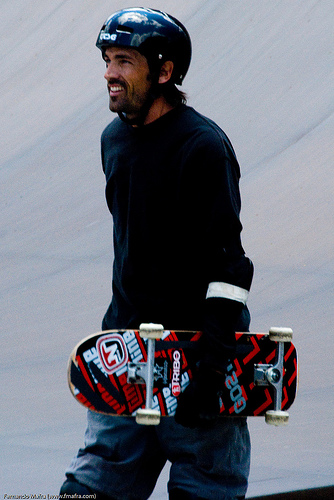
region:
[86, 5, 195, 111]
a black helmet is worn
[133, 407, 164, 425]
a white skateboard wheel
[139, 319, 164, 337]
a white skateboard wheel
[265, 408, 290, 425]
a white skateboard wheel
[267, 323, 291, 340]
a white skateboard wheel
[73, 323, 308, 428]
a colored skateboard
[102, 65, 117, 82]
a person's nose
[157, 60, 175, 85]
a person's ear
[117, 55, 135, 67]
a person's eye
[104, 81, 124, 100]
a person's mouth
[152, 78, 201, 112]
Long hair hanging down the nape of a man's neck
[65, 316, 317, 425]
A red, black, and white skateboard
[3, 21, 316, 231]
A half pipe behind a man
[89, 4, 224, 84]
A black helmet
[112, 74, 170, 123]
A helmet's strap hanging under a man's chin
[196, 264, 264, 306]
A white stripe on a man's arm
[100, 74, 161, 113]
A moustache and beard on a man's face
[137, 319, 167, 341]
A white wheel on a skateboard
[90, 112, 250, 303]
A black shirt on a man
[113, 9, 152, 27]
Light reflecting off a helmet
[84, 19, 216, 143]
Man with a helmet.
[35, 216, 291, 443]
Man holding the skateboard.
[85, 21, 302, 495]
Man wearing jeans and holding a skateboard.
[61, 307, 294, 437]
Black and red skateboard.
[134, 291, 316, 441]
Wheels on the skateboard.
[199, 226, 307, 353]
White stripe on the black shirt.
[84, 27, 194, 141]
Beard on the man.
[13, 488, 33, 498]
Words on the photo.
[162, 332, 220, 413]
Words on the skateboard.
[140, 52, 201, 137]
Long hair on the man.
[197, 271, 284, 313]
white band on black shirt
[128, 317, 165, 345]
white wheels on skateboard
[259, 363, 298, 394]
black screw on bottom of skateboard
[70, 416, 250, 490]
man wearing crumpled blue jeans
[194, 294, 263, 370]
black gloves on man's hand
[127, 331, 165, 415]
silver bracket on skate board wheel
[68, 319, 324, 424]
large skateboard in man's hand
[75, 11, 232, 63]
helmet on man's head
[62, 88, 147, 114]
beard on man's face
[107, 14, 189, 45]
shine on the black helmet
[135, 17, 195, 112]
man is wearing a helmet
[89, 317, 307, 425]
man is carrying a skateboard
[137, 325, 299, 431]
the wheels are white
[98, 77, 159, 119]
man has a beard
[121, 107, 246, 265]
man is wearing a black shirt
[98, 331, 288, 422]
the skateboard is black, red, and white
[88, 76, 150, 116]
the man is smiling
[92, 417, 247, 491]
man is wearing blue jeans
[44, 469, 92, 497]
knee pad for protection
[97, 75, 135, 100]
his teeth are white